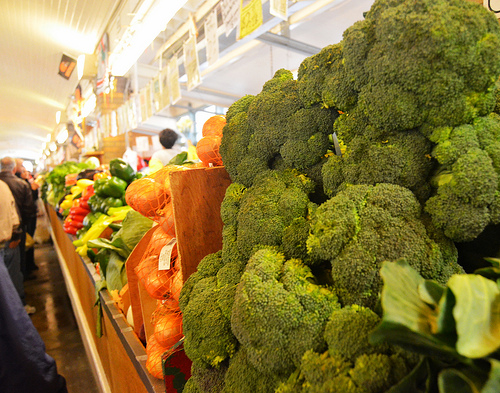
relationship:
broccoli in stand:
[226, 243, 336, 375] [38, 170, 220, 391]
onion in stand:
[122, 176, 169, 217] [38, 170, 220, 391]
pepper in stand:
[101, 177, 128, 197] [38, 170, 220, 391]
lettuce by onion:
[109, 208, 152, 264] [122, 176, 169, 217]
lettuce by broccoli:
[109, 208, 152, 264] [226, 243, 336, 375]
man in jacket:
[1, 153, 37, 288] [0, 172, 46, 238]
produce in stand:
[37, 2, 498, 389] [38, 170, 220, 391]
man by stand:
[1, 153, 37, 288] [38, 170, 220, 391]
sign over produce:
[164, 53, 184, 107] [37, 2, 498, 389]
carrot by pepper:
[94, 230, 120, 241] [101, 177, 128, 197]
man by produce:
[1, 153, 37, 288] [37, 2, 498, 389]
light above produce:
[107, 0, 179, 81] [37, 2, 498, 389]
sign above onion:
[164, 53, 184, 107] [122, 176, 169, 217]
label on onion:
[156, 236, 176, 272] [122, 176, 169, 217]